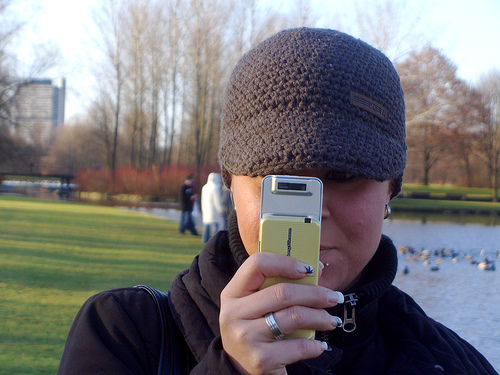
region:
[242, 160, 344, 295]
the woman is taking a picture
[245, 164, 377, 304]
the mobile phone slides apart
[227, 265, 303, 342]
a silver ring on the woman's hand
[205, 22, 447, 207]
a brown knit cap on her head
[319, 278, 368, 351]
the silver zipper near her chin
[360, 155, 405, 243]
a silver earring in her ear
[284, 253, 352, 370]
she has long pretty nails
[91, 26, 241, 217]
there are no leaves on the trees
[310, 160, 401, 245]
the woman's eye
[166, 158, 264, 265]
people in the background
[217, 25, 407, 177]
a brown knit cap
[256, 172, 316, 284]
a yellow cell phone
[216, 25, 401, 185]
a wool knit cap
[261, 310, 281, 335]
a silver ring on right hand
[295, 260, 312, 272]
the ladies nails are painted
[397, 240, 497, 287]
a flock of ducks swimming in the pond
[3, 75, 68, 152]
a tall building on the background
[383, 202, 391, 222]
the lady is wearing small hoop earings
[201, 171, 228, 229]
someone in the background wearing a white hoodie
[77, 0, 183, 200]
tall trees on the other side of the pond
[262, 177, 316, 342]
a yellow and grey handheld camera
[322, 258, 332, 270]
a lip piercing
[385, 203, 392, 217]
a small hooped earring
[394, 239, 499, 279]
a flock of ducks in a lake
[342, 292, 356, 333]
a dark stained zipper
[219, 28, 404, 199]
a knitted female hat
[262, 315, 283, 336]
a solid design ring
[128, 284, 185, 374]
a black leather strap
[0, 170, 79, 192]
a small bridge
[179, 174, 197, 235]
a man wearing a black long sleeved shirt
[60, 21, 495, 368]
woman taking photograph with cellphone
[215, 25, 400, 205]
knotted cap pulled low on head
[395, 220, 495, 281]
light and dark birds in water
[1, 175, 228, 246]
people standing on grassy area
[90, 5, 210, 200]
tall thin trees behind reddish bushes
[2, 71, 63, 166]
tall building behind park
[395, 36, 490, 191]
wide tree behind water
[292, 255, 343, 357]
manicured fingernails in black and white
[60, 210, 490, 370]
black jacket with collar pulled up on neck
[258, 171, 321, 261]
silver panel above yellow cellphone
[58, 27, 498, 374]
woman in brown hat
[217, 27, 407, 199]
brown hat is crocheted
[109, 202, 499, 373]
pond in park area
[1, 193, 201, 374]
grass in park area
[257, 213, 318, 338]
cell phone back is yellow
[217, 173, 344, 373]
cell phone in right hand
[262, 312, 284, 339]
silver ring on hand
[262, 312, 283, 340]
ring on ring finger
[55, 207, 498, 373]
woman wearing black jacket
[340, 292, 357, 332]
jacket has large zipper